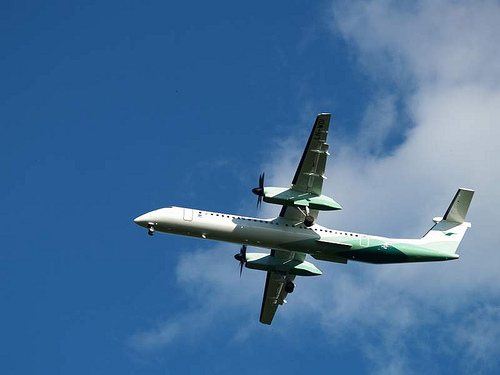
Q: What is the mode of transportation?
A: Plane.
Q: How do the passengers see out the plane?
A: Windows on side.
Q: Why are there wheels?
A: For landing and takeoff.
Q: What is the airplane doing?
A: Flying.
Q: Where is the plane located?
A: In the air.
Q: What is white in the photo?
A: Clouds.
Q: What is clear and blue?
A: The sky.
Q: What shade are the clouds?
A: White.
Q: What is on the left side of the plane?
A: A wing.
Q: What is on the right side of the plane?
A: The wing.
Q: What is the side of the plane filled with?
A: Windows.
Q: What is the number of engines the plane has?
A: Two.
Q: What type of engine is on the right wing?
A: Propellor.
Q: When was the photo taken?
A: Daytime.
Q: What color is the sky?
A: Blue.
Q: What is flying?
A: Plane.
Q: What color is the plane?
A: White and green.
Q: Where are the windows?
A: Side of plane.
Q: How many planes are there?
A: One.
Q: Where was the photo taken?
A: In the sky.